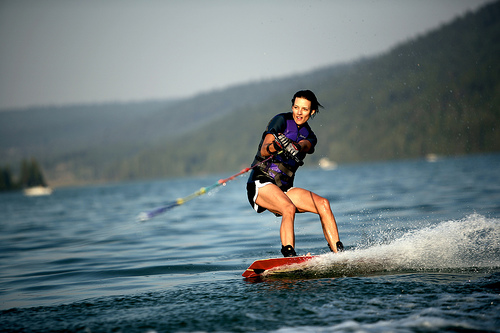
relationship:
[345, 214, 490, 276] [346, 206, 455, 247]
water sprays into air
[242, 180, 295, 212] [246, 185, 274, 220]
shorts have white trim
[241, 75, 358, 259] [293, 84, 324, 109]
woman has hair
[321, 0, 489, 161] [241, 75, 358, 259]
tall hill behind woman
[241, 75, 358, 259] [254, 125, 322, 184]
woman wearing purple lifevest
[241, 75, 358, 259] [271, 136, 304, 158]
woman wearing gloves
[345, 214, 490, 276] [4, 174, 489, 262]
water in sea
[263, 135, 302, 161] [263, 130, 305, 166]
hands are in tight grip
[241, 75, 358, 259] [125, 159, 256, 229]
woman holding onto tether rope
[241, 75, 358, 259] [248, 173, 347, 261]
woman has muscular legs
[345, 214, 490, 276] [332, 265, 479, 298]
water has wave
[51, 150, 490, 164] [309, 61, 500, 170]
horizon has trees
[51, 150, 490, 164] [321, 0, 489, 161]
horizon has tall hill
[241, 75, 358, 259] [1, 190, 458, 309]
woman surfing in river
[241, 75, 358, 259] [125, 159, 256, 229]
woman holds a tether rope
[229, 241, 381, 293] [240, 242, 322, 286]
ski board colored red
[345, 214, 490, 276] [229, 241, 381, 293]
water splashes next to ski board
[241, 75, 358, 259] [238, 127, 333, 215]
woman wearing suit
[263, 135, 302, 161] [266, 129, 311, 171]
hands are holding large handle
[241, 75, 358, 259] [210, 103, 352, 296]
woman bending backwards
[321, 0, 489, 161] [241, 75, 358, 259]
mountains are behind woman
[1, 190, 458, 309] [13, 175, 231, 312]
river water blue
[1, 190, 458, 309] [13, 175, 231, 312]
river waves are blue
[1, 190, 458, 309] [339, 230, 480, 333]
river waves are white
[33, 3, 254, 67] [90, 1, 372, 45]
clouds are in sky